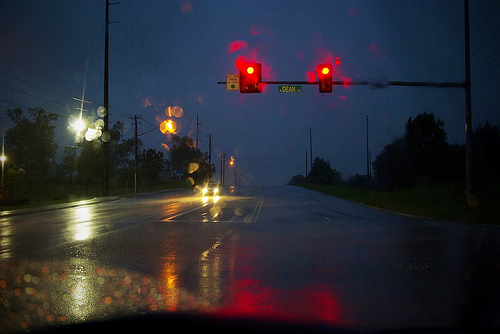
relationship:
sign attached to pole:
[211, 74, 243, 94] [398, 73, 472, 97]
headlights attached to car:
[203, 186, 221, 194] [202, 182, 217, 186]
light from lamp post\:
[241, 60, 262, 79] [66, 107, 112, 149]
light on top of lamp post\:
[241, 60, 262, 79] [66, 107, 112, 149]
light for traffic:
[241, 60, 262, 79] [246, 46, 345, 92]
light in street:
[241, 60, 262, 79] [261, 181, 397, 247]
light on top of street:
[241, 60, 262, 79] [261, 181, 397, 247]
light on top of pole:
[241, 60, 262, 79] [398, 73, 472, 97]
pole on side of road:
[398, 73, 472, 97] [199, 224, 264, 254]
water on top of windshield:
[130, 64, 185, 102] [1, 85, 294, 311]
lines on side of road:
[102, 13, 120, 63] [199, 224, 264, 254]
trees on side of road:
[4, 127, 51, 171] [199, 224, 264, 254]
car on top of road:
[202, 182, 217, 186] [199, 224, 264, 254]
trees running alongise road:
[4, 127, 51, 171] [199, 224, 264, 254]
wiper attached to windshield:
[156, 309, 207, 325] [1, 85, 294, 311]